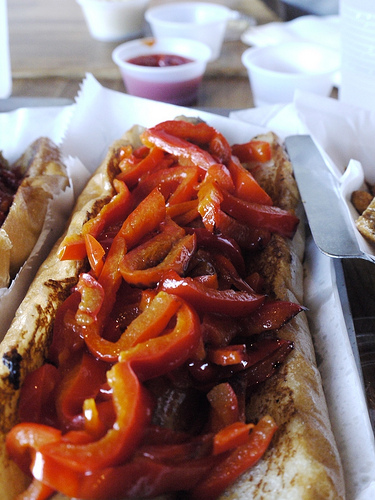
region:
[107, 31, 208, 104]
small condement cup of catsup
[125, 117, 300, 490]
sauteed red sweet peppers and onion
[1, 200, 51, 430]
toasted roll for sausag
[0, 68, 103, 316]
serrated waxed paper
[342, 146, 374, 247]
side of french fries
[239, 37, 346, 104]
empty beverage glass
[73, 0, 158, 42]
condiment cup with something white in it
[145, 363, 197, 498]
glimpse of sausage link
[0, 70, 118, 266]
part of a philly steak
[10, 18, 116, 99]
table top is brown wood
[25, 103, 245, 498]
a hot dog on a bun.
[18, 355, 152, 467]
grilled onion .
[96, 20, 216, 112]
a cup of kethcup.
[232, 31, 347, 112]
an empty plastic container.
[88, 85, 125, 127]
a piece of a wrapper.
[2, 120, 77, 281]
a piece of brown paper bag.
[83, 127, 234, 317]
grilled onions on a hot dog.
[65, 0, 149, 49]
a small container.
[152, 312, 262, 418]
sauce on a hot dog.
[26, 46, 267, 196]
A wrapper under a hot dog.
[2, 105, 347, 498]
a large sandwich from a restaurant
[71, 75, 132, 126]
white wax paper the sandwich is sitting on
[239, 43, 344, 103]
white plastic condiment cup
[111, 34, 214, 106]
condiment cup with ketchup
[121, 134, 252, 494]
roasted red bell peppers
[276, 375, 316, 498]
toasted bun of the sandwich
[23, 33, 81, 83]
brown table that the sandwich is on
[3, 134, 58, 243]
bread to the left of the sandwich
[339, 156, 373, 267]
french fried potatoes to the right of the sandwich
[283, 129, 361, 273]
metal tray the french fries are on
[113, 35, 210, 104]
Small clear cup with ketchup in it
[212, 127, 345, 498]
Bread is toasted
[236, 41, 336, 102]
Small clear cup next to small clear cup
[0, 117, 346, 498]
Veggie sandwich on white plastic paper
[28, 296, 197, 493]
Large red pepper next to red pepper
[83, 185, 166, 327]
Large red pepper next to red pepper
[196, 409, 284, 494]
Large red pepper next to red pepper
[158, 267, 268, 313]
Large red pepper next to red pepper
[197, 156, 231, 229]
Large red pepper next to red pepper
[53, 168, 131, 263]
Large red pepper next to red pepper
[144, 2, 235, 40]
Empty clear plastic cup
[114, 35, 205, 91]
Clear plastic cup filled with ketschup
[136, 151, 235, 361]
Fried red peppers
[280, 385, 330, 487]
Edge of toasted bun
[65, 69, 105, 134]
White paper food wrapper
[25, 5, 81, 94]
Wood table top surface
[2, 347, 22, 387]
Burnt stop on toasted bun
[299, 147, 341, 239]
Metal edge of food dish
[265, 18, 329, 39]
Square white napkin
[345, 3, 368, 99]
Ridges on side of clear plastic container